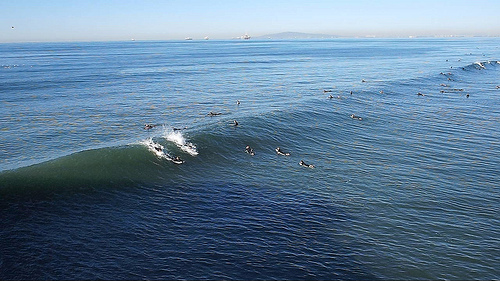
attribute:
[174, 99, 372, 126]
wave — small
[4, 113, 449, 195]
wave — large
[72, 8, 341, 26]
sky — clear blue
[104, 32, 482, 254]
wave — foamy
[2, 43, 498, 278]
ocean — calm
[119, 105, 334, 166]
waves — calm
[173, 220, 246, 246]
ripples — calm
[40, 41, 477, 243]
water — large, blue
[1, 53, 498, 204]
wave — large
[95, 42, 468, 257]
wave — splashing, white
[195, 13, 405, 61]
cloud — large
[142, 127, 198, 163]
splashes — white